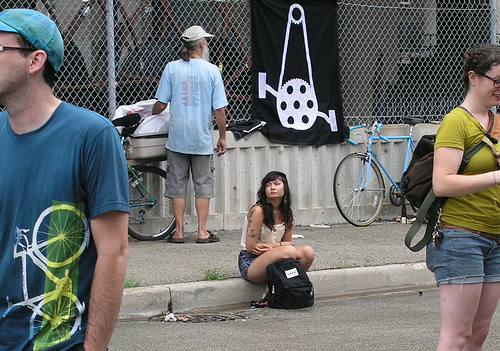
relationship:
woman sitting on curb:
[235, 169, 316, 309] [116, 259, 441, 327]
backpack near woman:
[262, 256, 316, 313] [235, 169, 316, 309]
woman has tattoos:
[235, 169, 316, 309] [246, 208, 260, 240]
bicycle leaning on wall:
[330, 113, 437, 228] [114, 119, 442, 239]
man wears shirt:
[2, 3, 133, 350] [2, 99, 130, 348]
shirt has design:
[2, 99, 130, 348] [2, 199, 92, 349]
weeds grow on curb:
[122, 265, 229, 290] [116, 259, 441, 327]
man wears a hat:
[2, 3, 133, 350] [0, 6, 67, 77]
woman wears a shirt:
[422, 44, 499, 349] [432, 106, 500, 240]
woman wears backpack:
[422, 44, 499, 349] [401, 109, 500, 256]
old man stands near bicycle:
[149, 23, 227, 245] [110, 110, 178, 242]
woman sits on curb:
[235, 169, 316, 309] [116, 259, 441, 327]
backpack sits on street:
[262, 256, 316, 313] [106, 286, 499, 350]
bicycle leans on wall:
[330, 113, 437, 228] [114, 119, 442, 239]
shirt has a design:
[2, 99, 130, 348] [2, 199, 92, 349]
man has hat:
[2, 3, 133, 350] [0, 6, 67, 77]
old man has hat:
[149, 23, 227, 245] [179, 23, 216, 42]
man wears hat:
[2, 3, 133, 350] [0, 6, 67, 77]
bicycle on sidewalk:
[330, 113, 437, 228] [119, 214, 433, 290]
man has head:
[2, 3, 133, 350] [0, 7, 66, 114]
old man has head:
[149, 23, 227, 245] [179, 24, 211, 66]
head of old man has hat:
[179, 24, 211, 66] [179, 23, 216, 42]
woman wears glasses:
[422, 44, 499, 349] [476, 70, 499, 91]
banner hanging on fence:
[248, 3, 348, 147] [1, 2, 500, 138]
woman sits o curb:
[235, 169, 316, 309] [116, 259, 441, 327]